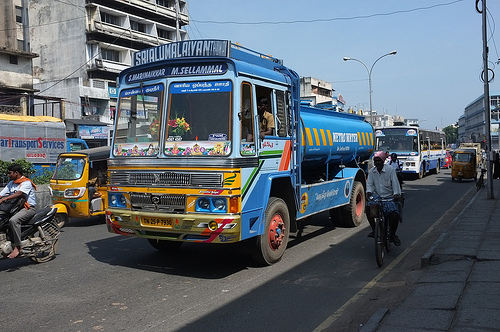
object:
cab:
[446, 148, 478, 180]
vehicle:
[42, 143, 114, 220]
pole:
[480, 6, 494, 200]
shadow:
[99, 240, 251, 279]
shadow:
[181, 175, 498, 330]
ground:
[3, 162, 495, 330]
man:
[357, 155, 397, 222]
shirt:
[309, 142, 425, 267]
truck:
[102, 42, 392, 254]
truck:
[401, 117, 440, 151]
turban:
[375, 152, 385, 159]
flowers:
[147, 116, 194, 138]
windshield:
[113, 81, 230, 159]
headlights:
[192, 195, 227, 220]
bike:
[353, 157, 423, 267]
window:
[107, 80, 121, 100]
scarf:
[20, 175, 31, 188]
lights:
[339, 39, 407, 143]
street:
[26, 254, 359, 329]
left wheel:
[345, 170, 369, 228]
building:
[27, 0, 198, 148]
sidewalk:
[370, 186, 499, 326]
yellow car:
[450, 148, 477, 184]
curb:
[356, 184, 484, 329]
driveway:
[377, 262, 493, 309]